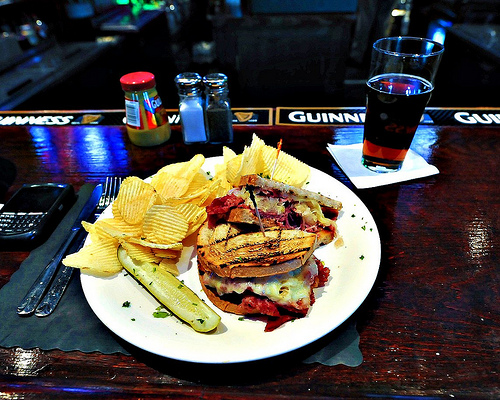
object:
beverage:
[360, 72, 434, 170]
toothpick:
[248, 191, 267, 237]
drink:
[360, 35, 446, 173]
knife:
[15, 184, 103, 316]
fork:
[15, 177, 123, 317]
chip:
[116, 176, 156, 223]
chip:
[153, 172, 191, 200]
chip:
[140, 204, 188, 245]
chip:
[61, 239, 122, 275]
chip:
[225, 156, 245, 184]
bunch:
[117, 175, 153, 226]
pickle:
[117, 243, 221, 333]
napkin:
[326, 142, 440, 190]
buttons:
[26, 215, 39, 220]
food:
[118, 248, 221, 334]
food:
[196, 223, 318, 278]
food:
[219, 184, 336, 228]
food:
[153, 207, 188, 243]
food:
[267, 153, 308, 184]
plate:
[78, 155, 382, 365]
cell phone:
[0, 181, 73, 243]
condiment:
[119, 71, 171, 146]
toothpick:
[270, 138, 283, 181]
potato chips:
[60, 240, 124, 274]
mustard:
[120, 72, 172, 147]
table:
[2, 104, 494, 395]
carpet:
[410, 198, 487, 338]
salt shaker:
[174, 72, 209, 145]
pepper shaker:
[202, 72, 233, 144]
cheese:
[267, 277, 310, 300]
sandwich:
[194, 173, 344, 332]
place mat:
[52, 312, 96, 350]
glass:
[361, 35, 446, 172]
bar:
[0, 0, 497, 397]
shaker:
[175, 72, 210, 146]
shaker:
[202, 73, 233, 145]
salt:
[178, 97, 206, 143]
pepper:
[205, 99, 232, 144]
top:
[275, 138, 283, 156]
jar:
[119, 71, 170, 148]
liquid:
[361, 73, 435, 164]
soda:
[362, 73, 435, 166]